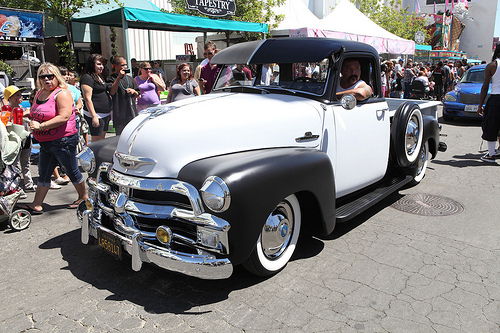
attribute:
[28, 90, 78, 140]
top — tank, pink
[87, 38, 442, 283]
pickup — old, black, white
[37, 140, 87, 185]
jeans — blue, capris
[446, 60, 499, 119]
car — blue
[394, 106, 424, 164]
tire — spare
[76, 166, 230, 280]
bumper — shiny, silver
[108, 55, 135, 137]
man — young 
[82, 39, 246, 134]
group — people 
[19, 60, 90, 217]
woman — walking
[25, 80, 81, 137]
shirt — pink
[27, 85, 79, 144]
pink shirt — pink 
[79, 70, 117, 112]
shirt — black 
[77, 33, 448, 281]
older car — older 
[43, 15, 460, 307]
truck — pickup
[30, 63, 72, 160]
woman — blond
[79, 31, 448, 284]
truck — pickup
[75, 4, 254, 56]
awning — green, behind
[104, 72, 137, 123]
shirt — black 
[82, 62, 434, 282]
truck — old, refurbished, black, white, pickup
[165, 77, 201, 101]
shirt — grey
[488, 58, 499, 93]
tank top — white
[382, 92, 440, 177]
tire — spare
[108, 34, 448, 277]
truck — restored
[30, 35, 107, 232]
woman — pushing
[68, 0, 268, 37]
awning — green, aqua, over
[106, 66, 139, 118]
shirt — black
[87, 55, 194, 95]
people — looking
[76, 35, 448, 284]
pickup truck — restored, early-model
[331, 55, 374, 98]
man — driving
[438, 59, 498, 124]
car — blue, modern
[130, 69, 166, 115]
shirt — purple 